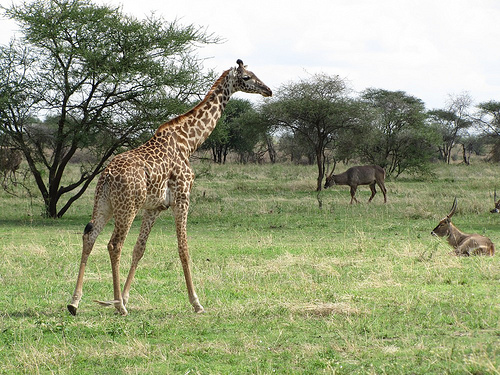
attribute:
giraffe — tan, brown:
[66, 57, 274, 314]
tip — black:
[71, 218, 101, 244]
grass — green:
[308, 262, 438, 337]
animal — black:
[430, 204, 495, 257]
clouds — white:
[312, 2, 495, 68]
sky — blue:
[250, 0, 390, 67]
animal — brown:
[319, 160, 395, 210]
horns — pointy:
[447, 196, 477, 240]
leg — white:
[107, 213, 132, 315]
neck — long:
[160, 96, 249, 168]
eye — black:
[237, 74, 254, 82]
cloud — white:
[82, 0, 496, 75]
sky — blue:
[0, 3, 495, 136]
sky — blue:
[232, 6, 463, 71]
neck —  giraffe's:
[91, 46, 269, 246]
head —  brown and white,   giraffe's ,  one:
[218, 60, 274, 101]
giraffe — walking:
[78, 51, 272, 336]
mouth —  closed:
[260, 81, 273, 101]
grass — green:
[279, 247, 367, 299]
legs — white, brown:
[61, 214, 211, 321]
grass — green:
[37, 144, 494, 374]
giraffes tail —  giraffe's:
[79, 179, 106, 244]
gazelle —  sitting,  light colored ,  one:
[428, 200, 495, 256]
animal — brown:
[324, 160, 393, 205]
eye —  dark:
[242, 72, 252, 82]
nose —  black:
[265, 89, 275, 96]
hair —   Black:
[85, 216, 92, 235]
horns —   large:
[447, 193, 461, 218]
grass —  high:
[10, 320, 496, 370]